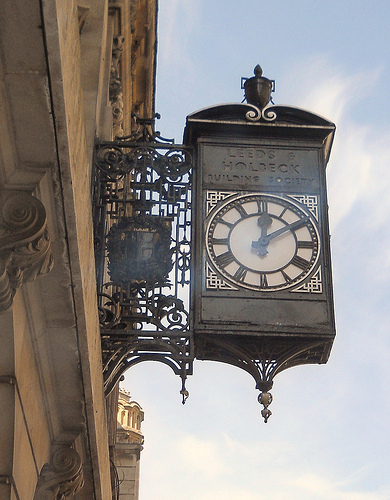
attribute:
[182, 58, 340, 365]
clock — dark brown, white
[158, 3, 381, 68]
sky — blue, white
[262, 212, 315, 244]
hand — black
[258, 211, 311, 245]
clock hand — black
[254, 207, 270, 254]
clock hand — black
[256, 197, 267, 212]
twelve — roman numeral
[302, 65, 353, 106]
clouds — pretty, white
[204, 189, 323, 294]
clock — metal, white, tall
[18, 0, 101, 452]
building — large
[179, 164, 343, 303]
clock — black, metal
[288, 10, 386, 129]
clouds — white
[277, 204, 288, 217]
roman numerals — black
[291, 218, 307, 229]
roman numerals — black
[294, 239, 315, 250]
roman numerals — black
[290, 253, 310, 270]
roman numerals — black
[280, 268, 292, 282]
roman numerals — black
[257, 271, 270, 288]
roman numerals — black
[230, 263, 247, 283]
roman numerals — black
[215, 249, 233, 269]
roman numerals — black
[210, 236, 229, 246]
roman numerals — black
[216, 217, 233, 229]
roman numerals — black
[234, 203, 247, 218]
roman numerals — black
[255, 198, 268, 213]
roman numerals — black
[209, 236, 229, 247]
number nine — roman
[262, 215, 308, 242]
hand — long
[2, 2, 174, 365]
building — tall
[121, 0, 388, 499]
sky — beautiful blue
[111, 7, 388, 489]
clouds — fuzzy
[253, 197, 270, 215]
number — roman numera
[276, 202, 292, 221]
number — roman numera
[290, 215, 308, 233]
number — roman numera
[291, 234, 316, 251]
number — roman numera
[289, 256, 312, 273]
number — roman numera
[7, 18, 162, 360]
building — old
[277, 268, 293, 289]
numeral — roman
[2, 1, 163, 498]
building — tan, dark brown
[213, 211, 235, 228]
ten — roman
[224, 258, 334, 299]
numerals — roman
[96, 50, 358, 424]
clock — old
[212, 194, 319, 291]
face — white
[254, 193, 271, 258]
hand — black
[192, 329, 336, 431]
bottom — pointed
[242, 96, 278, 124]
design — swirl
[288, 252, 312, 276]
numeral — roman